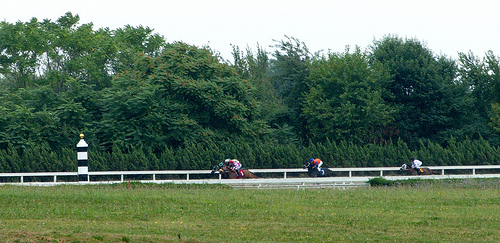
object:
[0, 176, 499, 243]
ground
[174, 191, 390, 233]
part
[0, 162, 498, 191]
metal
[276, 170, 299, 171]
part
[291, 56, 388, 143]
tree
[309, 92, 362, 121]
part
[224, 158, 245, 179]
people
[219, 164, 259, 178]
horse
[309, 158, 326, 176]
people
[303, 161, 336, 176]
horse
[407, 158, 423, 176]
people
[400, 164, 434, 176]
horse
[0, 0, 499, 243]
day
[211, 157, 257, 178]
front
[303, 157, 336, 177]
middle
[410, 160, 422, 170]
back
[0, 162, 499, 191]
race track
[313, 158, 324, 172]
clothing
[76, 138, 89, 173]
post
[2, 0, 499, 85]
sky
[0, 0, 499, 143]
backgroud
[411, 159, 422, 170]
clothing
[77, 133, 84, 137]
ball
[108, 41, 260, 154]
tree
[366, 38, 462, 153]
tree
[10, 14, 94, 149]
tree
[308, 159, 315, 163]
helmet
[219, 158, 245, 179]
outfit